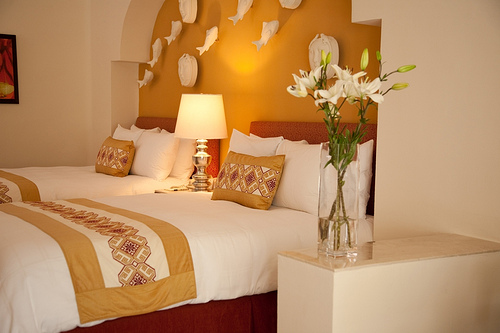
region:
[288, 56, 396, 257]
white lillies in a glass vase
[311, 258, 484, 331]
a white platform with a granite top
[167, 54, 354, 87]
white masks hanging on the wall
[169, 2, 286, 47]
decorative fish on the wall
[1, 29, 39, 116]
a painting on the wall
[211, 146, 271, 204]
a colorful pillow on the bed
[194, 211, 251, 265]
a white comforter on the bed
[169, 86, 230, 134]
a white lamp shade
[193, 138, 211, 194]
a silver base on a lamp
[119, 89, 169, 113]
a yellow recessed wall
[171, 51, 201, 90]
white ceramic face art piece hanging on a wall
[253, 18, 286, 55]
white ceramic fish art piece hanging on a wall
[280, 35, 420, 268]
white and green lilies in a vase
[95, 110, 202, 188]
four white pillows with a tan and white throw pillow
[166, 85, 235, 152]
illuminated lampshade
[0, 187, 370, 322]
white bedspread with brown and tan design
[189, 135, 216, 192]
silver lamp stand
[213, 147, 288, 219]
tan and brown throw pillow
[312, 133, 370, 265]
glass vase with green stems inside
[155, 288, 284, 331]
dusky red bed curtain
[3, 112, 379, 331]
twin beds next to each other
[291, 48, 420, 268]
flowers in tall vase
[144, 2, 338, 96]
ocean creatures wall hangings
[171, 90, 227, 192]
bedside lamp between beds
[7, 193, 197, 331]
bedspread with gold border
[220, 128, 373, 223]
pillows on bed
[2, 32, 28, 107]
art work on wall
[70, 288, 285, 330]
red bedskirt below mattress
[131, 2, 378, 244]
alcove painted gold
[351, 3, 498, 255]
white wall beside gold alcove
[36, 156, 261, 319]
the bedsheets are white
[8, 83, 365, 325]
the room has two beds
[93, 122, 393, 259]
the pillows are on the bed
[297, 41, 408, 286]
the flowers is in the vase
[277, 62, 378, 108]
the flowers are white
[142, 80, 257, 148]
the lamp is on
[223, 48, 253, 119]
the wall is orange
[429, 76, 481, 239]
the wall is white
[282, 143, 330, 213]
the pillow is white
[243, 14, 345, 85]
there are fishes on the wall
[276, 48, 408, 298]
Vase on the table.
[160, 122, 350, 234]
Pillow on the bed.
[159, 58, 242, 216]
Lamp on the table.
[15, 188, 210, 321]
Blanket on the bed.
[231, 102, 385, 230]
Headboard on the bed.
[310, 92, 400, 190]
Stems on the flowers.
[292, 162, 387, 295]
Water in the vase.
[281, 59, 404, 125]
Flowers on the stems.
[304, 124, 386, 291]
Clear vase with water.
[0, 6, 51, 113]
Picture on the wall.